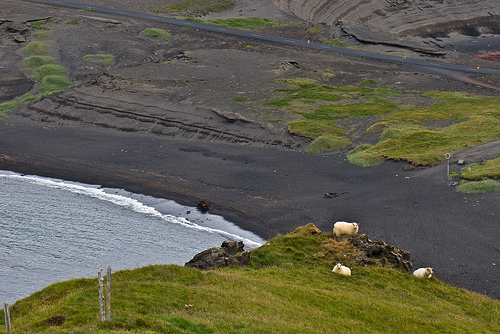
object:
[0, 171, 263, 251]
waves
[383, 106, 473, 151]
grass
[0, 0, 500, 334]
ground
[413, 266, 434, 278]
sheep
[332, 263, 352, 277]
sheep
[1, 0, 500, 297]
sandy seashore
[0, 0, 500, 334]
beach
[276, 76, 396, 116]
grass patch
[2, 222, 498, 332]
hillside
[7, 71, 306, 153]
erosion mark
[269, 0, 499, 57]
erosion mark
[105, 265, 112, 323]
trunks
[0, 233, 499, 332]
green landscape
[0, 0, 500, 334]
landscape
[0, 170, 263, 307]
water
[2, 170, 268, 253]
wave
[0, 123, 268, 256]
shore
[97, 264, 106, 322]
fenceposts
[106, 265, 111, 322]
fenceposts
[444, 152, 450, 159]
sign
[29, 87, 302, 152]
striations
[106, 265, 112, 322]
wooden poles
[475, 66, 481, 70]
sign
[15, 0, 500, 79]
roadway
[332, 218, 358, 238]
sheep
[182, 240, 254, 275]
outcrop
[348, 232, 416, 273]
outcrop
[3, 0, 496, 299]
sand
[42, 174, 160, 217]
foam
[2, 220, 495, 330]
mountain